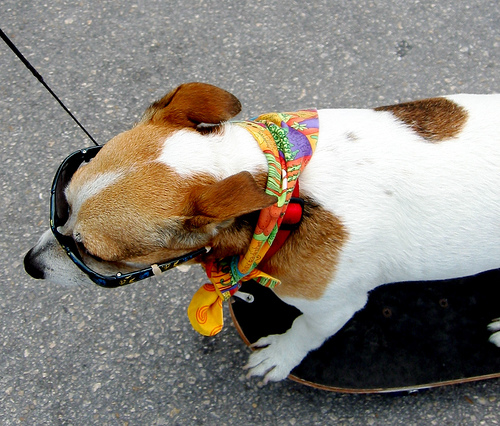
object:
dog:
[22, 81, 500, 385]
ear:
[192, 170, 277, 227]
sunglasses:
[49, 144, 216, 289]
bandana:
[187, 107, 319, 336]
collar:
[258, 178, 304, 265]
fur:
[325, 109, 488, 245]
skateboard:
[228, 267, 500, 395]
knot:
[206, 262, 254, 303]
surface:
[0, 0, 500, 426]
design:
[121, 256, 193, 286]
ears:
[150, 82, 277, 226]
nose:
[23, 247, 46, 281]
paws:
[241, 334, 300, 385]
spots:
[371, 97, 469, 145]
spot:
[343, 132, 361, 144]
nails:
[241, 340, 279, 386]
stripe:
[56, 169, 126, 232]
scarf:
[184, 259, 282, 336]